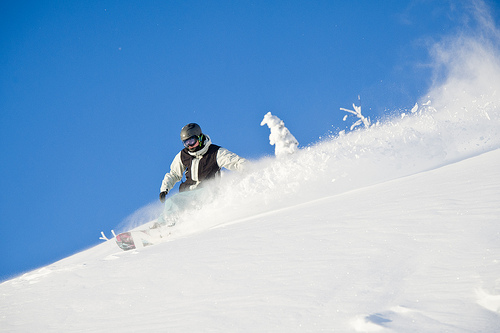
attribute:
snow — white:
[34, 66, 496, 327]